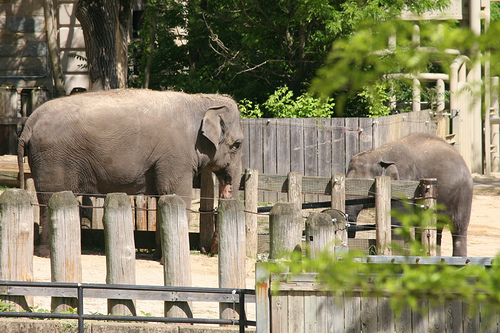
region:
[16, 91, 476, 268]
The two gray elephants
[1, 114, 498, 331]
The low wooden fence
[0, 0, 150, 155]
The wall background on the left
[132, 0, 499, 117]
The green vegetation in the background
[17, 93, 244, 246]
The gray mature jumbo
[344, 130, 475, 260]
The tusk-less baby elephant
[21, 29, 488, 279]
two elephants standing together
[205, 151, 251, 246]
the trunk is thick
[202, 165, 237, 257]
the trunk is discolored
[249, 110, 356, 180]
the fence is made of wood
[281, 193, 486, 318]
the leaves are blurry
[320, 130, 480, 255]
the elephant is smaller than the other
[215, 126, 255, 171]
the eye is open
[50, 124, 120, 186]
the skin is wrinkled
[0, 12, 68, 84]
shadow on the wall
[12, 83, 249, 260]
gray elephant near tree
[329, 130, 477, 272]
small young elephant in enclosure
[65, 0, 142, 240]
thick brown tree in elephant enclosure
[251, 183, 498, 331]
green leafy tree branch near elephants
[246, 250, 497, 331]
gray and light brown wooden fence around elephant enclosure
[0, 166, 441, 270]
gray and light brown fence near elephants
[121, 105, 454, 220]
gray wooden fence behind elephants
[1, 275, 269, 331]
black metal railing near elephant enclosure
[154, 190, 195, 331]
thick white and gray wooden fence post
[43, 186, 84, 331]
thick white and gray wooden fence post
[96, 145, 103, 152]
gray skin on elephant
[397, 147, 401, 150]
gray skin on elephant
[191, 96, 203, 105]
gray skin on elephant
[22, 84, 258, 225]
elephant in the zoo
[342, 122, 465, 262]
elephant in the zoo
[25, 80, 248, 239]
elephant in the zoo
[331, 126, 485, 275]
elephant in the zoo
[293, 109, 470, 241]
elephant in the zoo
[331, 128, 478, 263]
elephant in the zoo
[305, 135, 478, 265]
elephant in the zoo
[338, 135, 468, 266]
elephant in the zoo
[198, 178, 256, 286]
post is made of wood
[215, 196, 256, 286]
post is brown in color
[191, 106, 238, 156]
elephant has ear on head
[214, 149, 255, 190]
elephant has long trunk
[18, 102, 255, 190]
elephant is grey in color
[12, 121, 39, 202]
elephant has a hanging tail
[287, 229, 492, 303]
leaves of tree are green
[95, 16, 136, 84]
trunk of tree is brown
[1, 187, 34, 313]
wooden post of fence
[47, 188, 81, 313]
wooden post of fence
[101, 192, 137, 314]
wooden post of fence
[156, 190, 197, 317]
wooden post of fence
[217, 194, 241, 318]
wooden post of fence